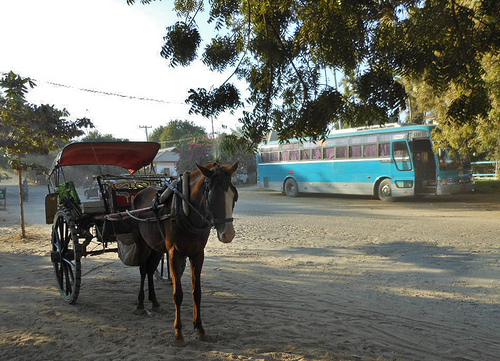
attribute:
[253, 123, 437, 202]
bus — parked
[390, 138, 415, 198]
door — open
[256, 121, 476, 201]
bus — blue, silver, blue and white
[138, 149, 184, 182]
building — white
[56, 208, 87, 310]
wheel — large, black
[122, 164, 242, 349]
horse — dark brown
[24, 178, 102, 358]
wheel — big